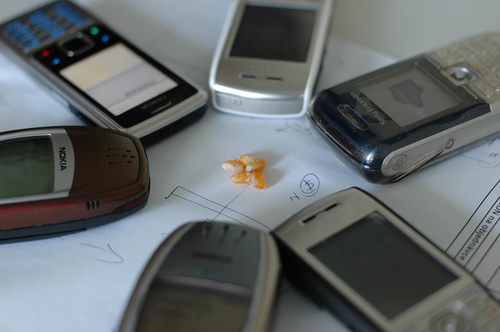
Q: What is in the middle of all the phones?
A: Popcorn.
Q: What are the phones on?
A: A paper.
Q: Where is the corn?
A: In the middle.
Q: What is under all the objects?
A: A paper.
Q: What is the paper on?
A: The table.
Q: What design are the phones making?
A: A flower.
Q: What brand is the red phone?
A: Nokia.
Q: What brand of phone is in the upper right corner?
A: Sony Ericsson.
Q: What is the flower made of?
A: Cell phones.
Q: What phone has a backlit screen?
A: Upper left corner.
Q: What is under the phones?
A: Paper.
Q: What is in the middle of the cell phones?
A: Popcorn kernels.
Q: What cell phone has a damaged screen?
A: Sony Ericsson.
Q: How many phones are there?
A: 6 phones.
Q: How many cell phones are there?
A: Six.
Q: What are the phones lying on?
A: Paper.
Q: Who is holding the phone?
A: No one.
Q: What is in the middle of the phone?
A: Kernel.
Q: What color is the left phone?
A: Maroon.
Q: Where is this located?
A: Desk.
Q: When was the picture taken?
A: Daytime.